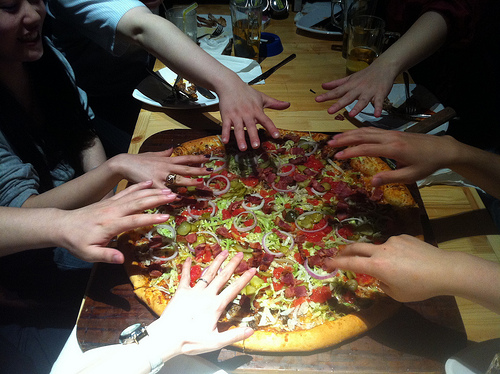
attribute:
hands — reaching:
[162, 247, 260, 354]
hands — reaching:
[68, 177, 180, 270]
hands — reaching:
[117, 145, 216, 204]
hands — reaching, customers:
[213, 83, 293, 152]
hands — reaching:
[313, 63, 397, 124]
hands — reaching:
[327, 127, 454, 189]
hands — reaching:
[322, 231, 452, 310]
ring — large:
[163, 172, 177, 186]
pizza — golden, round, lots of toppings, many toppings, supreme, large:
[123, 123, 425, 354]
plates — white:
[131, 62, 243, 104]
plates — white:
[176, 11, 245, 48]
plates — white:
[295, 5, 362, 41]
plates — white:
[339, 78, 451, 140]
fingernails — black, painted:
[202, 152, 212, 161]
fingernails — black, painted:
[205, 167, 212, 173]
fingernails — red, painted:
[194, 175, 202, 184]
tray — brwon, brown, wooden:
[76, 123, 474, 373]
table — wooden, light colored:
[47, 2, 500, 373]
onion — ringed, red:
[232, 210, 256, 232]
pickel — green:
[175, 218, 192, 236]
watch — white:
[116, 321, 166, 373]